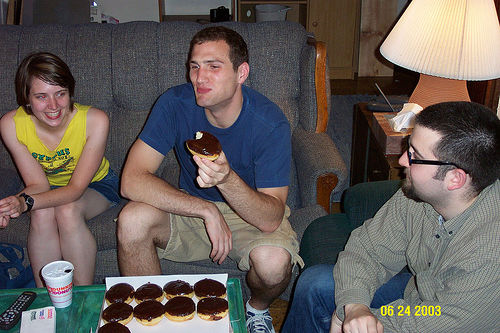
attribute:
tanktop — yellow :
[18, 103, 110, 185]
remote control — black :
[0, 288, 38, 330]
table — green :
[0, 274, 253, 331]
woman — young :
[9, 41, 134, 281]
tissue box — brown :
[368, 108, 414, 161]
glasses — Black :
[400, 135, 470, 182]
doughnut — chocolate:
[184, 130, 232, 172]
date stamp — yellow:
[380, 305, 441, 316]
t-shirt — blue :
[136, 83, 291, 203]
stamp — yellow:
[377, 301, 447, 321]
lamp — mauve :
[367, 65, 478, 172]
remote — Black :
[5, 285, 41, 330]